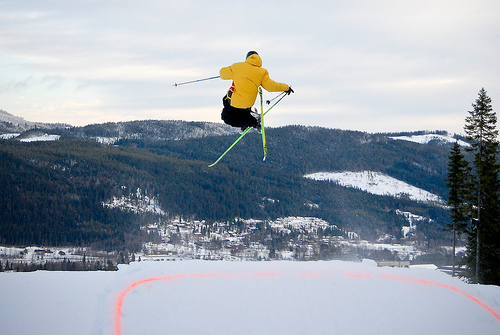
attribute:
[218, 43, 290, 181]
skier — in air, jumping, performing trick, doing stunt, performing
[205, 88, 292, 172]
skis — yellow, green, crossed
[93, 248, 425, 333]
snow — white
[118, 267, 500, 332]
line — red, orange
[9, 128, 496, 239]
hills — rolling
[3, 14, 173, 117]
sky — cloudy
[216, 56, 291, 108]
jacket — yellow, heavy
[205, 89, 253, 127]
pants — black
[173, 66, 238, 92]
pole — black, white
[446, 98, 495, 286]
trees — grouped, tall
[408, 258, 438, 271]
building — white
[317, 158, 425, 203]
clearing — white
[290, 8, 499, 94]
clouds — grey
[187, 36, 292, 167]
person — in air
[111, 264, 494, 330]
paint — bright